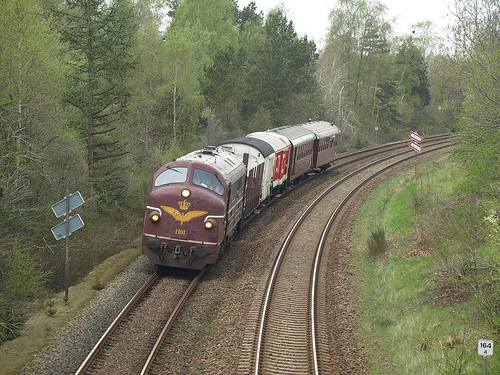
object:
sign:
[50, 191, 86, 217]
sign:
[47, 213, 90, 242]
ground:
[446, 119, 456, 134]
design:
[158, 200, 211, 238]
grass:
[1, 238, 101, 350]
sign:
[479, 334, 498, 359]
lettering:
[477, 340, 493, 349]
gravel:
[148, 138, 361, 373]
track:
[237, 137, 462, 375]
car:
[217, 128, 293, 220]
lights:
[179, 188, 193, 197]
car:
[140, 145, 247, 273]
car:
[296, 120, 341, 170]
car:
[266, 123, 316, 186]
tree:
[49, 0, 143, 281]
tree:
[138, 28, 207, 157]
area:
[8, 1, 500, 317]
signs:
[411, 127, 421, 156]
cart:
[214, 137, 276, 219]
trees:
[1, 0, 88, 263]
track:
[74, 130, 460, 375]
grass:
[359, 156, 499, 373]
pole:
[63, 189, 71, 299]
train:
[140, 120, 337, 272]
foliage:
[445, 0, 498, 143]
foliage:
[0, 0, 433, 372]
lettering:
[269, 152, 289, 181]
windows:
[293, 140, 315, 158]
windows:
[317, 133, 337, 148]